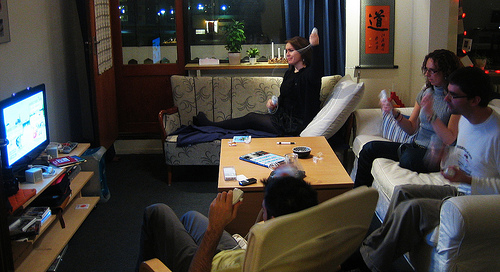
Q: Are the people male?
A: No, they are both male and female.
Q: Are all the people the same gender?
A: No, they are both male and female.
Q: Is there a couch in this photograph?
A: Yes, there is a couch.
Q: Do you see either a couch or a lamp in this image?
A: Yes, there is a couch.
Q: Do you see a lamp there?
A: No, there are no lamps.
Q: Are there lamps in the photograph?
A: No, there are no lamps.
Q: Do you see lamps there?
A: No, there are no lamps.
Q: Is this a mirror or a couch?
A: This is a couch.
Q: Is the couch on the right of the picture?
A: Yes, the couch is on the right of the image.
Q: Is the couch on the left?
A: No, the couch is on the right of the image.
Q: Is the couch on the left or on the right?
A: The couch is on the right of the image.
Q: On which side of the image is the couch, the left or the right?
A: The couch is on the right of the image.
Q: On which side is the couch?
A: The couch is on the right of the image.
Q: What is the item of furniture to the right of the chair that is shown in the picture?
A: The piece of furniture is a couch.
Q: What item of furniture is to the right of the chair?
A: The piece of furniture is a couch.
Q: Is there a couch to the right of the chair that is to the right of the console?
A: Yes, there is a couch to the right of the chair.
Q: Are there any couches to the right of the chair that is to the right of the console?
A: Yes, there is a couch to the right of the chair.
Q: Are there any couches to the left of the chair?
A: No, the couch is to the right of the chair.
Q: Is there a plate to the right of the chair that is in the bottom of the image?
A: No, there is a couch to the right of the chair.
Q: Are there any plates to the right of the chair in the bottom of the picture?
A: No, there is a couch to the right of the chair.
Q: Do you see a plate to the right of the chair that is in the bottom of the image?
A: No, there is a couch to the right of the chair.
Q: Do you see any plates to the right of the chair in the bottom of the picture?
A: No, there is a couch to the right of the chair.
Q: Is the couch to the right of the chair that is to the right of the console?
A: Yes, the couch is to the right of the chair.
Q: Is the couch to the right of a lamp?
A: No, the couch is to the right of the chair.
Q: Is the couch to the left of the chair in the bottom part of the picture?
A: No, the couch is to the right of the chair.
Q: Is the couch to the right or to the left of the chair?
A: The couch is to the right of the chair.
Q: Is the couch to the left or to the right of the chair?
A: The couch is to the right of the chair.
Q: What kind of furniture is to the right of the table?
A: The piece of furniture is a couch.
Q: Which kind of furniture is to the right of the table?
A: The piece of furniture is a couch.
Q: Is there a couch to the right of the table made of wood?
A: Yes, there is a couch to the right of the table.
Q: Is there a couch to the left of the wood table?
A: No, the couch is to the right of the table.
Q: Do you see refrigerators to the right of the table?
A: No, there is a couch to the right of the table.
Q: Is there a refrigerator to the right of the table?
A: No, there is a couch to the right of the table.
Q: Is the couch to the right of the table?
A: Yes, the couch is to the right of the table.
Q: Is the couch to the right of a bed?
A: No, the couch is to the right of the table.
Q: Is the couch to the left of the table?
A: No, the couch is to the right of the table.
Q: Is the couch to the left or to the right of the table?
A: The couch is to the right of the table.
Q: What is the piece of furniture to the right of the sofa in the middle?
A: The piece of furniture is a couch.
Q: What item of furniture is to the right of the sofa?
A: The piece of furniture is a couch.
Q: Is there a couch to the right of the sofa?
A: Yes, there is a couch to the right of the sofa.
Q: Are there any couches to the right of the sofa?
A: Yes, there is a couch to the right of the sofa.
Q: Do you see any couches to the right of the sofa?
A: Yes, there is a couch to the right of the sofa.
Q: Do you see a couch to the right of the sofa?
A: Yes, there is a couch to the right of the sofa.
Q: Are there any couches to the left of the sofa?
A: No, the couch is to the right of the sofa.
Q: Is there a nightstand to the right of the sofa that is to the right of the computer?
A: No, there is a couch to the right of the sofa.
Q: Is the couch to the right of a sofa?
A: Yes, the couch is to the right of a sofa.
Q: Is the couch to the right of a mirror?
A: No, the couch is to the right of a sofa.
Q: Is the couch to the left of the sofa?
A: No, the couch is to the right of the sofa.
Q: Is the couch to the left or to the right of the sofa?
A: The couch is to the right of the sofa.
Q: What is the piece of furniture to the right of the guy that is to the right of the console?
A: The piece of furniture is a couch.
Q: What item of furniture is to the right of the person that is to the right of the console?
A: The piece of furniture is a couch.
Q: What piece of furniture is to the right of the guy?
A: The piece of furniture is a couch.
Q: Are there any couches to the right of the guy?
A: Yes, there is a couch to the right of the guy.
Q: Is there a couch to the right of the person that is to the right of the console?
A: Yes, there is a couch to the right of the guy.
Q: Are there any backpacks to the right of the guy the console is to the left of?
A: No, there is a couch to the right of the guy.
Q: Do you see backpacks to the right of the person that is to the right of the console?
A: No, there is a couch to the right of the guy.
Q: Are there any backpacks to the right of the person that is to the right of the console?
A: No, there is a couch to the right of the guy.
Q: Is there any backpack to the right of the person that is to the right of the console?
A: No, there is a couch to the right of the guy.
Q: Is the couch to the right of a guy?
A: Yes, the couch is to the right of a guy.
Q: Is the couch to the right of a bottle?
A: No, the couch is to the right of a guy.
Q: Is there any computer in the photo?
A: Yes, there is a computer.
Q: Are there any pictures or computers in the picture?
A: Yes, there is a computer.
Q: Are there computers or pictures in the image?
A: Yes, there is a computer.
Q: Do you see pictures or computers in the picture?
A: Yes, there is a computer.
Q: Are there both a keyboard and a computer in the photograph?
A: No, there is a computer but no keyboards.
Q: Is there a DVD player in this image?
A: No, there are no DVD players.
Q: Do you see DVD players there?
A: No, there are no DVD players.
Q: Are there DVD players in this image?
A: No, there are no DVD players.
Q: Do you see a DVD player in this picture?
A: No, there are no DVD players.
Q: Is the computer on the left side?
A: Yes, the computer is on the left of the image.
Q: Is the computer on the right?
A: No, the computer is on the left of the image.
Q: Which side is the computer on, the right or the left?
A: The computer is on the left of the image.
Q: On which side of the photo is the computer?
A: The computer is on the left of the image.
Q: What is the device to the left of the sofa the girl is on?
A: The device is a computer.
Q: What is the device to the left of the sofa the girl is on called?
A: The device is a computer.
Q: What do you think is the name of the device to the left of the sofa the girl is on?
A: The device is a computer.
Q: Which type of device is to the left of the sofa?
A: The device is a computer.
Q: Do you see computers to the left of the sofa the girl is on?
A: Yes, there is a computer to the left of the sofa.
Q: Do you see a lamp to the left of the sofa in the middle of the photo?
A: No, there is a computer to the left of the sofa.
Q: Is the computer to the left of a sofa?
A: Yes, the computer is to the left of a sofa.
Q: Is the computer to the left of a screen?
A: No, the computer is to the left of a sofa.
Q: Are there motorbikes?
A: No, there are no motorbikes.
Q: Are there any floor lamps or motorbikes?
A: No, there are no motorbikes or floor lamps.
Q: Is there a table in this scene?
A: Yes, there is a table.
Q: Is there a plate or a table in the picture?
A: Yes, there is a table.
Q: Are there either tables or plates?
A: Yes, there is a table.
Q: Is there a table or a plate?
A: Yes, there is a table.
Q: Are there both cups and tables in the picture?
A: No, there is a table but no cups.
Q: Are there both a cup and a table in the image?
A: No, there is a table but no cups.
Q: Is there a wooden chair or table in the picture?
A: Yes, there is a wood table.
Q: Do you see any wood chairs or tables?
A: Yes, there is a wood table.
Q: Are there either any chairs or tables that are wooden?
A: Yes, the table is wooden.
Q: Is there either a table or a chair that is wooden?
A: Yes, the table is wooden.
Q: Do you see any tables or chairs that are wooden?
A: Yes, the table is wooden.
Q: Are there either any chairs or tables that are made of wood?
A: Yes, the table is made of wood.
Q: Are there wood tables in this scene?
A: Yes, there is a wood table.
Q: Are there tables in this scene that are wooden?
A: Yes, there is a table that is wooden.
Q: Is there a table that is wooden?
A: Yes, there is a table that is wooden.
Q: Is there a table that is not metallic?
A: Yes, there is a wooden table.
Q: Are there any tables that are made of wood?
A: Yes, there is a table that is made of wood.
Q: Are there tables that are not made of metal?
A: Yes, there is a table that is made of wood.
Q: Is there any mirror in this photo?
A: No, there are no mirrors.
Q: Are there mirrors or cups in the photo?
A: No, there are no mirrors or cups.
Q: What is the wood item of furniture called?
A: The piece of furniture is a table.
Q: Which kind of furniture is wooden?
A: The furniture is a table.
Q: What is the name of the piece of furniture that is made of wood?
A: The piece of furniture is a table.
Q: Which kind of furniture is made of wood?
A: The furniture is a table.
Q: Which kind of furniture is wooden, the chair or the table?
A: The table is wooden.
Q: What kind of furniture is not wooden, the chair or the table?
A: The chair is not wooden.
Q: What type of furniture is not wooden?
A: The furniture is a chair.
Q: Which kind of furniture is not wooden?
A: The furniture is a chair.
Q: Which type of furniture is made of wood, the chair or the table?
A: The table is made of wood.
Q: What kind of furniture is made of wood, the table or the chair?
A: The table is made of wood.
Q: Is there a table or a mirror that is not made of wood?
A: No, there is a table but it is made of wood.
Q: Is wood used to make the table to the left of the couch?
A: Yes, the table is made of wood.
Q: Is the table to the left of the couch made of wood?
A: Yes, the table is made of wood.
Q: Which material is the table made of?
A: The table is made of wood.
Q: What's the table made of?
A: The table is made of wood.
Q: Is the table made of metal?
A: No, the table is made of wood.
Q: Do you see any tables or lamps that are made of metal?
A: No, there is a table but it is made of wood.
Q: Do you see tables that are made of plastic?
A: No, there is a table but it is made of wood.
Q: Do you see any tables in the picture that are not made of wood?
A: No, there is a table but it is made of wood.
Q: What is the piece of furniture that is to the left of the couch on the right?
A: The piece of furniture is a table.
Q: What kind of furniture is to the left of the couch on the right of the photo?
A: The piece of furniture is a table.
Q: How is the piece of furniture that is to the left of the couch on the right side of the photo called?
A: The piece of furniture is a table.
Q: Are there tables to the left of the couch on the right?
A: Yes, there is a table to the left of the couch.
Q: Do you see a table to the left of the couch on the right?
A: Yes, there is a table to the left of the couch.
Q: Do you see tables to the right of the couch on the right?
A: No, the table is to the left of the couch.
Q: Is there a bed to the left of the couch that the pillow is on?
A: No, there is a table to the left of the couch.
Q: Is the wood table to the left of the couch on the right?
A: Yes, the table is to the left of the couch.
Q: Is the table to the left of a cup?
A: No, the table is to the left of the couch.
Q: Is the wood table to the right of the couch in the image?
A: No, the table is to the left of the couch.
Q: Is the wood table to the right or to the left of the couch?
A: The table is to the left of the couch.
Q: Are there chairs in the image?
A: Yes, there is a chair.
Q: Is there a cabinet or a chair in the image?
A: Yes, there is a chair.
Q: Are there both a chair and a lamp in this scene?
A: No, there is a chair but no lamps.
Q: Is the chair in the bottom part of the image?
A: Yes, the chair is in the bottom of the image.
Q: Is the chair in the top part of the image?
A: No, the chair is in the bottom of the image.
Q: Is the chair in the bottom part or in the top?
A: The chair is in the bottom of the image.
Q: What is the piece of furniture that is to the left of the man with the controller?
A: The piece of furniture is a chair.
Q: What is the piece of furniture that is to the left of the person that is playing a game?
A: The piece of furniture is a chair.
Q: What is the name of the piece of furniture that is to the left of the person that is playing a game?
A: The piece of furniture is a chair.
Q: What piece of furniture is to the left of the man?
A: The piece of furniture is a chair.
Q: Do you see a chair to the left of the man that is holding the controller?
A: Yes, there is a chair to the left of the man.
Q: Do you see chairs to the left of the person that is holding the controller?
A: Yes, there is a chair to the left of the man.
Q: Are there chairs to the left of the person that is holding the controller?
A: Yes, there is a chair to the left of the man.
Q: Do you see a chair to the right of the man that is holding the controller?
A: No, the chair is to the left of the man.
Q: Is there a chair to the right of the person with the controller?
A: No, the chair is to the left of the man.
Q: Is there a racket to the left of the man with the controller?
A: No, there is a chair to the left of the man.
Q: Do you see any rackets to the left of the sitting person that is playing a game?
A: No, there is a chair to the left of the man.